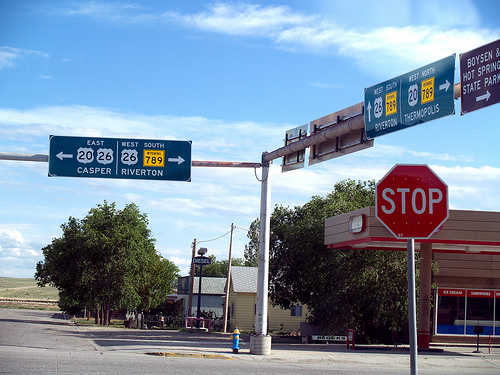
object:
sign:
[438, 289, 497, 298]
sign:
[142, 146, 164, 168]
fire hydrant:
[230, 327, 242, 354]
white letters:
[428, 187, 444, 216]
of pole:
[249, 148, 277, 355]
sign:
[346, 212, 366, 234]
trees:
[55, 202, 180, 326]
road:
[0, 308, 91, 375]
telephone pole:
[221, 222, 238, 336]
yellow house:
[223, 265, 308, 332]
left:
[55, 150, 74, 161]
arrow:
[475, 89, 492, 102]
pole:
[401, 241, 423, 375]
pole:
[196, 262, 204, 330]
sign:
[312, 334, 346, 341]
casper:
[77, 166, 112, 175]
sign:
[46, 135, 193, 184]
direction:
[167, 154, 185, 165]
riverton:
[121, 168, 165, 177]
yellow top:
[232, 325, 242, 335]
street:
[42, 319, 104, 341]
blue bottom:
[231, 334, 241, 350]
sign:
[456, 38, 500, 118]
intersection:
[0, 332, 147, 375]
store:
[322, 205, 498, 351]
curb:
[241, 357, 384, 364]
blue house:
[173, 274, 228, 327]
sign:
[176, 275, 193, 295]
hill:
[0, 276, 35, 308]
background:
[0, 199, 180, 325]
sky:
[0, 0, 358, 100]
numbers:
[98, 151, 112, 161]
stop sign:
[371, 160, 450, 245]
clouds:
[196, 5, 294, 35]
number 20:
[78, 150, 92, 160]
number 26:
[123, 152, 137, 162]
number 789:
[421, 87, 433, 101]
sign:
[359, 54, 458, 142]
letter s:
[381, 188, 395, 215]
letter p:
[428, 187, 443, 214]